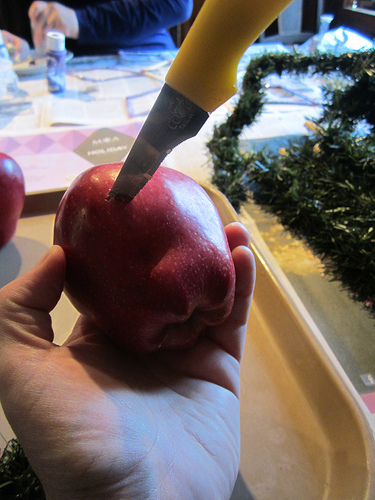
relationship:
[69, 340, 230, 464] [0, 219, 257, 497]
palm of hand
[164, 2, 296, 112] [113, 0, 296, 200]
handle on knife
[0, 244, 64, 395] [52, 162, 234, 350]
thumb on apple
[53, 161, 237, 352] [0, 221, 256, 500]
apple in the hand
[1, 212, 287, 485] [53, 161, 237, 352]
hand holding an apple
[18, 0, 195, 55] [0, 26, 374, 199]
person sitting at the table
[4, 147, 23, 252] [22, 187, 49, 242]
apple on a tray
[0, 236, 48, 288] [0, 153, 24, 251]
shadow of the apple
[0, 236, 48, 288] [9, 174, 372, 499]
shadow on the tray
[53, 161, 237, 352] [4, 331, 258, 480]
apple in the hand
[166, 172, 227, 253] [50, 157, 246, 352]
reflection on the apple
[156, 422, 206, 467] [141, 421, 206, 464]
reflection on the palm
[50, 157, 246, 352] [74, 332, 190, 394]
apple casting shadow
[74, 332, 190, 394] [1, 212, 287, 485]
shadow in the hand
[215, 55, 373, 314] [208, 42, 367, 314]
needles on garland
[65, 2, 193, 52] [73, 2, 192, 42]
sleeve of shirt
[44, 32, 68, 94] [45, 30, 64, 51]
tube with cap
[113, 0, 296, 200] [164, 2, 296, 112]
knife with handle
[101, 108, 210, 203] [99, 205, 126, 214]
blade in skin